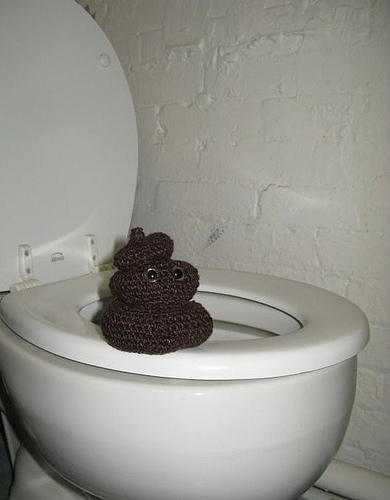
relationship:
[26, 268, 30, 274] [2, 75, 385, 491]
bolt on toilet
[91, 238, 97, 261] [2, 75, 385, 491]
bolt on toilet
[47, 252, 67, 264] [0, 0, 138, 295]
logo on toilet lid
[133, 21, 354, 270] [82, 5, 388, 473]
cracks in wall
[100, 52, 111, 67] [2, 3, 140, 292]
bolt on cover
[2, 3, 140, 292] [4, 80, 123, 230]
cover of seat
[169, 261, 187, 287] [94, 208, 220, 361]
eye of doll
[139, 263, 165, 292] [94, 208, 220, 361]
eye of doll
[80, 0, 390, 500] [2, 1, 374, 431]
toilet wall of toilet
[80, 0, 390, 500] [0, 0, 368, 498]
toilet wall of toilet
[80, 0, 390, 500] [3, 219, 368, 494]
toilet wall of toilet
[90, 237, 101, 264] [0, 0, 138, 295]
bolt on toilet lid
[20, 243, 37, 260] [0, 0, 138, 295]
bolt on toilet lid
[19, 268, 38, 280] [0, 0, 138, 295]
bolt on toilet lid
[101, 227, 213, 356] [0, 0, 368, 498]
black frog on toilet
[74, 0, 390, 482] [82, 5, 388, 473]
brick on wall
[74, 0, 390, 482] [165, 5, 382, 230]
brick on wall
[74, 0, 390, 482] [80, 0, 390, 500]
brick on toilet wall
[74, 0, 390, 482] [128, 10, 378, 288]
brick on wall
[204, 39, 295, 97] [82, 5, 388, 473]
brick on wall